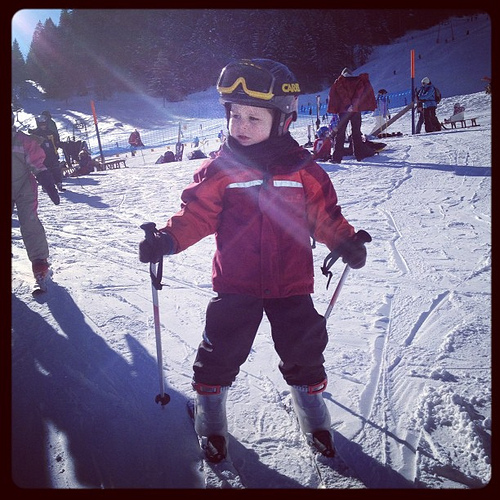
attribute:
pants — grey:
[186, 291, 340, 392]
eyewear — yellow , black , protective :
[212, 56, 275, 104]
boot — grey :
[296, 377, 341, 457]